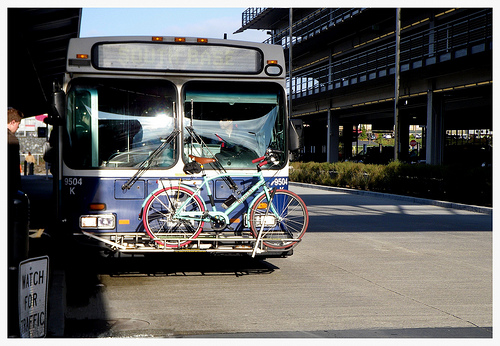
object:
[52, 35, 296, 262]
bus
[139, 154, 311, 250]
bike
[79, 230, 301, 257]
carrier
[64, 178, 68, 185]
numbers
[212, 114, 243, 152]
driver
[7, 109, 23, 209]
man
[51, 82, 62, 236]
door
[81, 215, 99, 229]
light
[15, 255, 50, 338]
sign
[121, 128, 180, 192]
wiper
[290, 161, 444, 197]
shrub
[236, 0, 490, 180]
building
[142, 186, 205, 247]
wheel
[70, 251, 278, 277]
shadow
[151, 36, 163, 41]
top light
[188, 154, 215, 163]
seat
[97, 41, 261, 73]
destination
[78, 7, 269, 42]
sky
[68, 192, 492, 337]
street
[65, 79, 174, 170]
windshield